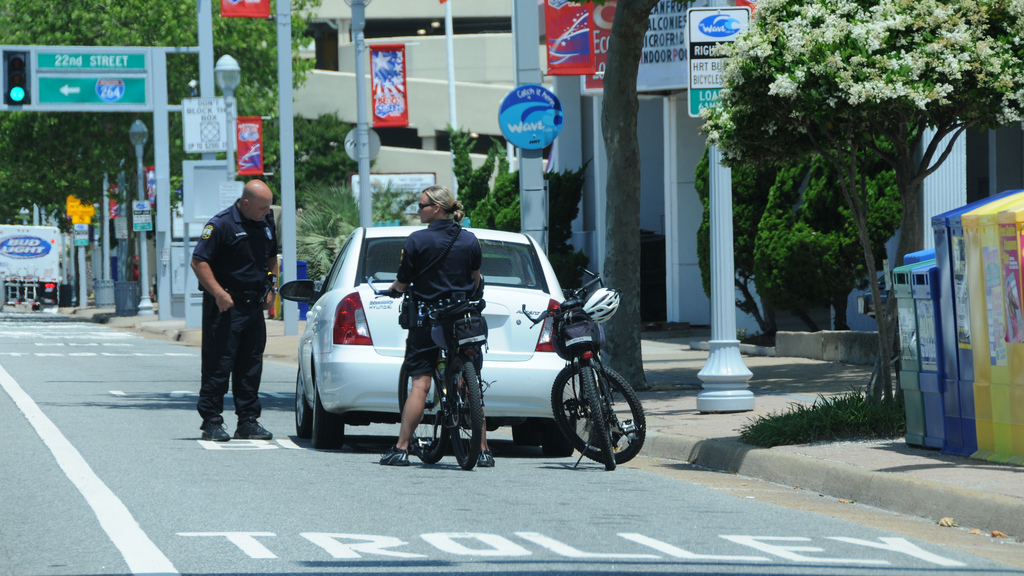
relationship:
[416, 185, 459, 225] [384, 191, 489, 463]
head on officer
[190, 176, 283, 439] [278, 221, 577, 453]
policeman beside car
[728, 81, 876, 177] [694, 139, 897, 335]
leaves on tree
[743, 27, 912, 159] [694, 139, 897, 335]
leaves on tree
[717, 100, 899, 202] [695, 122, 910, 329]
leaves on tree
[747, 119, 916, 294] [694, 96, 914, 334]
leaves on tree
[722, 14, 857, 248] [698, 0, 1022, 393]
leaves on tree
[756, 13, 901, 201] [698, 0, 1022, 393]
leaves on tree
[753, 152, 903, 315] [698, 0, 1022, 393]
leaves on tree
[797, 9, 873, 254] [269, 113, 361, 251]
leaves on tree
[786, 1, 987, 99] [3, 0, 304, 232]
leaves on tree